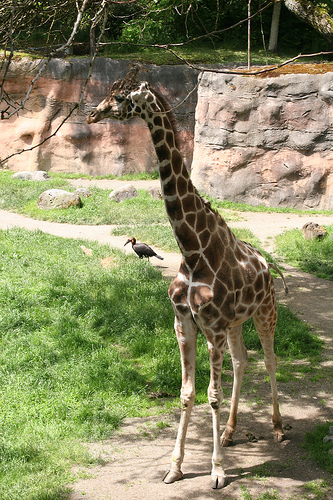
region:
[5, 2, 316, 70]
This is forest vegetation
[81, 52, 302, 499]
This is a giraffe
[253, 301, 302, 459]
Leg of a giraffe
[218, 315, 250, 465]
Leg of a giraffe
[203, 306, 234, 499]
Leg of a giraffe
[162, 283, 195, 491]
Leg of a giraffe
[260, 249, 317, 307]
Tail of a giraffe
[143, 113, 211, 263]
Neck of a giraffe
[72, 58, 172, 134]
Head of a giraffe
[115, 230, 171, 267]
This is a bird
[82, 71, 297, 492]
a giraffe face left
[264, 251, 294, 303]
tail of a giraffe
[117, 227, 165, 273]
a bird in a giraffe's pen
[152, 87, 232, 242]
long neck of giraffe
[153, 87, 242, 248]
mane over neck of giraffe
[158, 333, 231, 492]
front legs of giraffe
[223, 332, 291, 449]
back legs of giraffe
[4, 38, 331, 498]
the pen of giraffe is fenced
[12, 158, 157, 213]
small stones in a pen of a giraffe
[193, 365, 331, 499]
shadows cast on ground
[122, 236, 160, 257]
black bird on path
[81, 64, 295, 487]
giraffe looking to the side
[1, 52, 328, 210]
rock wall behind giraffe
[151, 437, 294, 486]
four hooves of giraffe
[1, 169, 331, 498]
patches of grass in the enclosure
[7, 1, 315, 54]
trees above rock wall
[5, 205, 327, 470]
path giraffe is walking on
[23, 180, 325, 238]
rocks in the enclosure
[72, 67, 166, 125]
head of the giraffe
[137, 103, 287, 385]
brown spots on the giraffe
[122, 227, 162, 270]
small black bird on ground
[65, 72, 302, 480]
large giraffe in foreground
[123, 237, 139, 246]
red head of bird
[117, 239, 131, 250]
long beak of bird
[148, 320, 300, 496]
legs of giraffe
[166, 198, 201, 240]
brown and white spots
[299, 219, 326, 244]
rock on ground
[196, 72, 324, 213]
large rock wall on side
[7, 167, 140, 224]
group of rocks on grass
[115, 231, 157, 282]
bird on dirt path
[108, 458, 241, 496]
two front hooves of giraffe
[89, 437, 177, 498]
shadow on the ground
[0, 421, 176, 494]
green grass with dirt patch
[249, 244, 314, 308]
small tail of a giraffe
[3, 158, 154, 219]
rocks in the grass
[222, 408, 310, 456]
pebbles on the ground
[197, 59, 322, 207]
a tall rock wall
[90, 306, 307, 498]
four legs of a giraffe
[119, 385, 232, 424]
a giraffes two front knees